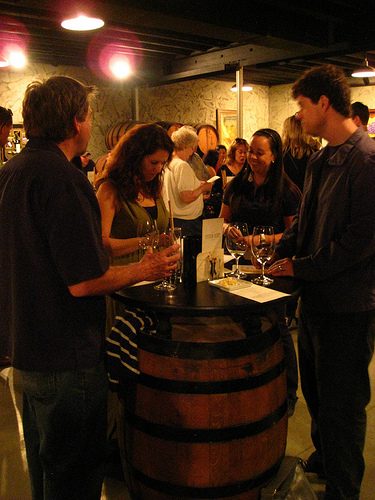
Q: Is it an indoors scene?
A: Yes, it is indoors.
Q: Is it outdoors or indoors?
A: It is indoors.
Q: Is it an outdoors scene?
A: No, it is indoors.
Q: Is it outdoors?
A: No, it is indoors.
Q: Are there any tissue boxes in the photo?
A: No, there are no tissue boxes.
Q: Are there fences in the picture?
A: No, there are no fences.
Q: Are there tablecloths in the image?
A: No, there are no tablecloths.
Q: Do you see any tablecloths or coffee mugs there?
A: No, there are no tablecloths or coffee mugs.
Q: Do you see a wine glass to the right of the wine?
A: Yes, there are wine glasses to the right of the wine.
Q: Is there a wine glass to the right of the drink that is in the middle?
A: Yes, there are wine glasses to the right of the wine.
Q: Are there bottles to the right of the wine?
A: No, there are wine glasses to the right of the wine.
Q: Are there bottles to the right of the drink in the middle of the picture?
A: No, there are wine glasses to the right of the wine.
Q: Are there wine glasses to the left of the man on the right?
A: Yes, there are wine glasses to the left of the man.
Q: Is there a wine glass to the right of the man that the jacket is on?
A: No, the wine glasses are to the left of the man.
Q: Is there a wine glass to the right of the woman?
A: Yes, there are wine glasses to the right of the woman.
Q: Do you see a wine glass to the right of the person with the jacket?
A: Yes, there are wine glasses to the right of the woman.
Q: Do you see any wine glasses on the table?
A: Yes, there are wine glasses on the table.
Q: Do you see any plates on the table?
A: No, there are wine glasses on the table.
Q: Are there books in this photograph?
A: No, there are no books.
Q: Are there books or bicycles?
A: No, there are no books or bicycles.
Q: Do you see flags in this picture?
A: No, there are no flags.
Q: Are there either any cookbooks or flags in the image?
A: No, there are no flags or cookbooks.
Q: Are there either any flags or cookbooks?
A: No, there are no flags or cookbooks.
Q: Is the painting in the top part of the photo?
A: Yes, the painting is in the top of the image.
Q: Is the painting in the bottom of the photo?
A: No, the painting is in the top of the image.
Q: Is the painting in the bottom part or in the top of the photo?
A: The painting is in the top of the image.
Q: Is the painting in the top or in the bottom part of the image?
A: The painting is in the top of the image.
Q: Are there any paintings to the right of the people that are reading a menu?
A: Yes, there is a painting to the right of the people.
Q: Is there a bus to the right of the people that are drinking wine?
A: No, there is a painting to the right of the people.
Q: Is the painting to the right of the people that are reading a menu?
A: Yes, the painting is to the right of the people.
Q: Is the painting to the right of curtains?
A: No, the painting is to the right of the people.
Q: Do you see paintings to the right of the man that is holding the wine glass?
A: Yes, there is a painting to the right of the man.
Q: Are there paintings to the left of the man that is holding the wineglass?
A: No, the painting is to the right of the man.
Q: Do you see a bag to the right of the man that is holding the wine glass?
A: No, there is a painting to the right of the man.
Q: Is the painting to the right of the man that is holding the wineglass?
A: Yes, the painting is to the right of the man.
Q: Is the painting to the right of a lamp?
A: No, the painting is to the right of the man.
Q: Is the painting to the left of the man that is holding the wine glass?
A: No, the painting is to the right of the man.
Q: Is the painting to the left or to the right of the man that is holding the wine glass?
A: The painting is to the right of the man.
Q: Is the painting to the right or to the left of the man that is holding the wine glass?
A: The painting is to the right of the man.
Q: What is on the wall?
A: The painting is on the wall.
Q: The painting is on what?
A: The painting is on the wall.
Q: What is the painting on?
A: The painting is on the wall.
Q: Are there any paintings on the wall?
A: Yes, there is a painting on the wall.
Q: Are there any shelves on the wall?
A: No, there is a painting on the wall.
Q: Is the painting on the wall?
A: Yes, the painting is on the wall.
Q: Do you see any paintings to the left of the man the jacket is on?
A: Yes, there is a painting to the left of the man.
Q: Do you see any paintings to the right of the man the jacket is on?
A: No, the painting is to the left of the man.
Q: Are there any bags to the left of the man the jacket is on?
A: No, there is a painting to the left of the man.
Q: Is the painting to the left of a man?
A: Yes, the painting is to the left of a man.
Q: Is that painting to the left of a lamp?
A: No, the painting is to the left of a man.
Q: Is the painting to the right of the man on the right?
A: No, the painting is to the left of the man.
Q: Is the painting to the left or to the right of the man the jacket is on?
A: The painting is to the left of the man.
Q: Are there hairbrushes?
A: No, there are no hairbrushes.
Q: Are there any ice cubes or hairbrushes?
A: No, there are no hairbrushes or ice cubes.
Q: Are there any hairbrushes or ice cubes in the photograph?
A: No, there are no hairbrushes or ice cubes.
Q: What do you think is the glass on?
A: The glass is on the table.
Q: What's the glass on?
A: The glass is on the table.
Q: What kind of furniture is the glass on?
A: The glass is on the table.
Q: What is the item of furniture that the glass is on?
A: The piece of furniture is a table.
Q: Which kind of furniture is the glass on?
A: The glass is on the table.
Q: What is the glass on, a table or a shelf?
A: The glass is on a table.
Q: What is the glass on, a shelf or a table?
A: The glass is on a table.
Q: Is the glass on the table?
A: Yes, the glass is on the table.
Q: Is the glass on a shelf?
A: No, the glass is on the table.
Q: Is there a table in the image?
A: Yes, there is a table.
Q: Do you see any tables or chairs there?
A: Yes, there is a table.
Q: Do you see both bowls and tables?
A: No, there is a table but no bowls.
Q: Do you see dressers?
A: No, there are no dressers.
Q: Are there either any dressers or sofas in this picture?
A: No, there are no dressers or sofas.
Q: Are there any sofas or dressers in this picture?
A: No, there are no dressers or sofas.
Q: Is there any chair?
A: No, there are no chairs.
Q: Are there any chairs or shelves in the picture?
A: No, there are no chairs or shelves.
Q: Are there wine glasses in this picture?
A: Yes, there is a wine glass.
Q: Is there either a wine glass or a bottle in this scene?
A: Yes, there is a wine glass.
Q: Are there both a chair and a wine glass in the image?
A: No, there is a wine glass but no chairs.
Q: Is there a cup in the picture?
A: No, there are no cups.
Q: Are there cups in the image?
A: No, there are no cups.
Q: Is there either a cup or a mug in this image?
A: No, there are no cups or mugs.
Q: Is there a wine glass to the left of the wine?
A: Yes, there is a wine glass to the left of the wine.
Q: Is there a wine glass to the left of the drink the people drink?
A: Yes, there is a wine glass to the left of the wine.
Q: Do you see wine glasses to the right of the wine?
A: No, the wine glass is to the left of the wine.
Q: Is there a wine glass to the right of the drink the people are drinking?
A: No, the wine glass is to the left of the wine.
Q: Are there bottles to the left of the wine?
A: No, there is a wine glass to the left of the wine.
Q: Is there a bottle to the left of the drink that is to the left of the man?
A: No, there is a wine glass to the left of the wine.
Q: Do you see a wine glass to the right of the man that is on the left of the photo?
A: Yes, there is a wine glass to the right of the man.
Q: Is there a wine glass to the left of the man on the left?
A: No, the wine glass is to the right of the man.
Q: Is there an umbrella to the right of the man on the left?
A: No, there is a wine glass to the right of the man.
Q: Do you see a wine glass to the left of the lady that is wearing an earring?
A: Yes, there is a wine glass to the left of the lady.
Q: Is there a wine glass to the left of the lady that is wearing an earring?
A: Yes, there is a wine glass to the left of the lady.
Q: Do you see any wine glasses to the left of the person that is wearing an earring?
A: Yes, there is a wine glass to the left of the lady.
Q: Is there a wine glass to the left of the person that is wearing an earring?
A: Yes, there is a wine glass to the left of the lady.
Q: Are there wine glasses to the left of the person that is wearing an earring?
A: Yes, there is a wine glass to the left of the lady.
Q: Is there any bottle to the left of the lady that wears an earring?
A: No, there is a wine glass to the left of the lady.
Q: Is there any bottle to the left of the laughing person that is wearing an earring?
A: No, there is a wine glass to the left of the lady.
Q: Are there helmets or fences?
A: No, there are no fences or helmets.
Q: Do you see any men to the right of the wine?
A: Yes, there is a man to the right of the wine.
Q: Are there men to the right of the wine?
A: Yes, there is a man to the right of the wine.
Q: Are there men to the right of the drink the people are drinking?
A: Yes, there is a man to the right of the wine.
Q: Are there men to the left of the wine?
A: No, the man is to the right of the wine.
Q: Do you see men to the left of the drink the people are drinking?
A: No, the man is to the right of the wine.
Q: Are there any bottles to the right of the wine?
A: No, there is a man to the right of the wine.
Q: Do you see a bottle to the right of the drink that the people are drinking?
A: No, there is a man to the right of the wine.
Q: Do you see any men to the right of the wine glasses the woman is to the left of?
A: Yes, there is a man to the right of the wine glasses.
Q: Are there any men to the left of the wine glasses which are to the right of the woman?
A: No, the man is to the right of the wine glasses.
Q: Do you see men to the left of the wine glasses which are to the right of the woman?
A: No, the man is to the right of the wine glasses.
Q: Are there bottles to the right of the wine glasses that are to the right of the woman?
A: No, there is a man to the right of the wine glasses.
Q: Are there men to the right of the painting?
A: Yes, there is a man to the right of the painting.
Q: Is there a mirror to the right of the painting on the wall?
A: No, there is a man to the right of the painting.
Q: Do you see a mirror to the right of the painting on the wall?
A: No, there is a man to the right of the painting.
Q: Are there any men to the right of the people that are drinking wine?
A: Yes, there is a man to the right of the people.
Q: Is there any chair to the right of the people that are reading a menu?
A: No, there is a man to the right of the people.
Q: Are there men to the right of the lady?
A: Yes, there is a man to the right of the lady.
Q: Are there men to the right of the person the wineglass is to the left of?
A: Yes, there is a man to the right of the lady.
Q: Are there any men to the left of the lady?
A: No, the man is to the right of the lady.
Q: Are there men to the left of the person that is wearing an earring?
A: No, the man is to the right of the lady.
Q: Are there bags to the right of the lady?
A: No, there is a man to the right of the lady.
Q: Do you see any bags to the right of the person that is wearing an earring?
A: No, there is a man to the right of the lady.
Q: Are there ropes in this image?
A: No, there are no ropes.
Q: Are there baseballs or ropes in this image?
A: No, there are no ropes or baseballs.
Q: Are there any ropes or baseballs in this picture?
A: No, there are no ropes or baseballs.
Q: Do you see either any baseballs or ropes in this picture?
A: No, there are no ropes or baseballs.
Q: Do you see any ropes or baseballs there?
A: No, there are no ropes or baseballs.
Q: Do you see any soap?
A: No, there are no soaps.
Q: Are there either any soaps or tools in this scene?
A: No, there are no soaps or tools.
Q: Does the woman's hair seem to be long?
A: Yes, the hair is long.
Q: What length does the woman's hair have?
A: The hair has long length.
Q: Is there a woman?
A: Yes, there is a woman.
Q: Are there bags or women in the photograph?
A: Yes, there is a woman.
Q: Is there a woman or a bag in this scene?
A: Yes, there is a woman.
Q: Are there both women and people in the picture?
A: Yes, there are both a woman and a person.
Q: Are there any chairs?
A: No, there are no chairs.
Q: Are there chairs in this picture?
A: No, there are no chairs.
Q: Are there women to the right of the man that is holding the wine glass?
A: Yes, there is a woman to the right of the man.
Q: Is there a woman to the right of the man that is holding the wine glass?
A: Yes, there is a woman to the right of the man.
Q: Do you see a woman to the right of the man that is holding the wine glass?
A: Yes, there is a woman to the right of the man.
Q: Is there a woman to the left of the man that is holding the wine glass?
A: No, the woman is to the right of the man.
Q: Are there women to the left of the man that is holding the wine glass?
A: No, the woman is to the right of the man.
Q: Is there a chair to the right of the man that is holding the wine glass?
A: No, there is a woman to the right of the man.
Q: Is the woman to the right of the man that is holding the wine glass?
A: Yes, the woman is to the right of the man.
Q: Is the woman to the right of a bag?
A: No, the woman is to the right of the man.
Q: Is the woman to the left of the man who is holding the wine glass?
A: No, the woman is to the right of the man.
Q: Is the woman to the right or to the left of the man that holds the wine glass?
A: The woman is to the right of the man.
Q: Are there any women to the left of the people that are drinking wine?
A: Yes, there is a woman to the left of the people.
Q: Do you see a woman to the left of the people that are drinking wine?
A: Yes, there is a woman to the left of the people.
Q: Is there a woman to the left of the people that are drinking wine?
A: Yes, there is a woman to the left of the people.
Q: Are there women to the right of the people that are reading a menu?
A: No, the woman is to the left of the people.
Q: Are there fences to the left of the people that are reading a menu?
A: No, there is a woman to the left of the people.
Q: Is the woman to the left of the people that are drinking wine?
A: Yes, the woman is to the left of the people.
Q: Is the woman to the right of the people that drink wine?
A: No, the woman is to the left of the people.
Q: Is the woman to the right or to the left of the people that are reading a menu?
A: The woman is to the left of the people.